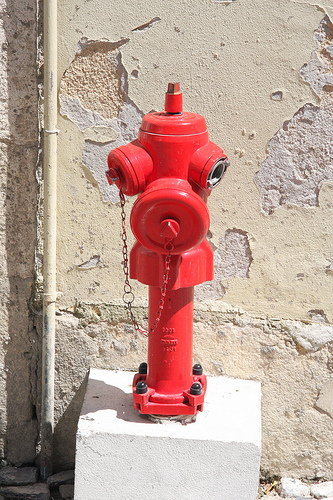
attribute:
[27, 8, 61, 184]
pole — white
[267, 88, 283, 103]
wall damage — cracked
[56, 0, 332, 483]
wall — behind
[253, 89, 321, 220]
wall cracks — colors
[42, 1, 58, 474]
conduit — attached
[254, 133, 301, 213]
paint — chipping